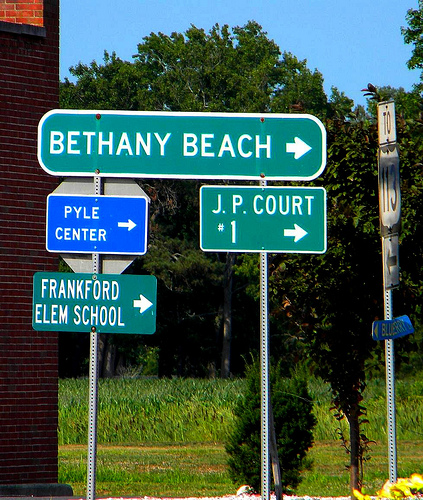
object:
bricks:
[10, 82, 22, 90]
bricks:
[11, 96, 25, 106]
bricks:
[15, 151, 31, 160]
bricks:
[24, 180, 36, 188]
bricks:
[23, 193, 36, 202]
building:
[0, 0, 61, 498]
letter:
[134, 131, 152, 158]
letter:
[181, 132, 199, 158]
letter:
[217, 133, 237, 159]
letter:
[255, 133, 271, 159]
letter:
[67, 129, 81, 156]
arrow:
[117, 218, 138, 232]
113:
[381, 163, 398, 212]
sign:
[376, 98, 397, 147]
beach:
[181, 131, 272, 160]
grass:
[57, 442, 421, 497]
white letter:
[82, 130, 97, 156]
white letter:
[115, 131, 134, 157]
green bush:
[223, 348, 319, 495]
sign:
[36, 107, 328, 182]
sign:
[45, 192, 149, 255]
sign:
[31, 271, 158, 336]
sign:
[371, 313, 415, 341]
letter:
[48, 129, 65, 156]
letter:
[153, 132, 172, 157]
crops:
[58, 372, 422, 446]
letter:
[97, 131, 114, 157]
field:
[58, 440, 423, 498]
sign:
[198, 184, 327, 256]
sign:
[382, 233, 400, 291]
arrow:
[285, 136, 314, 161]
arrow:
[283, 222, 309, 244]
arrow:
[132, 293, 154, 315]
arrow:
[385, 248, 397, 276]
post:
[259, 252, 269, 498]